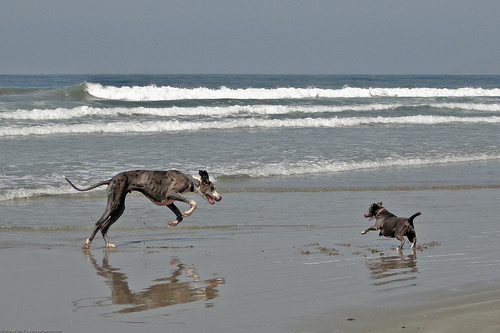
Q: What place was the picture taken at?
A: It was taken at the beach.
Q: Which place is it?
A: It is a beach.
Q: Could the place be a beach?
A: Yes, it is a beach.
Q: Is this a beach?
A: Yes, it is a beach.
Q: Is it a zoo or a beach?
A: It is a beach.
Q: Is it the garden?
A: No, it is the beach.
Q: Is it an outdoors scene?
A: Yes, it is outdoors.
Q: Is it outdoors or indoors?
A: It is outdoors.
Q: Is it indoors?
A: No, it is outdoors.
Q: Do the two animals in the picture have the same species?
A: Yes, all the animals are dogs.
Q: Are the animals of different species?
A: No, all the animals are dogs.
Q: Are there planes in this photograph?
A: No, there are no planes.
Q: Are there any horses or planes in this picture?
A: No, there are no planes or horses.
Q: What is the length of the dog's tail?
A: The tail is long.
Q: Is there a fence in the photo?
A: No, there are no fences.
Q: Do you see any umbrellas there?
A: No, there are no umbrellas.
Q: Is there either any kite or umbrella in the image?
A: No, there are no umbrellas or kites.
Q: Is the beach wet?
A: Yes, the beach is wet.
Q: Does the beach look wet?
A: Yes, the beach is wet.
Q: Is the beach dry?
A: No, the beach is wet.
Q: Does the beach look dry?
A: No, the beach is wet.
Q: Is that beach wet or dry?
A: The beach is wet.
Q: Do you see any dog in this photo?
A: Yes, there is a dog.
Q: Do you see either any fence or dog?
A: Yes, there is a dog.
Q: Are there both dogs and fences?
A: No, there is a dog but no fences.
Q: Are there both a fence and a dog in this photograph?
A: No, there is a dog but no fences.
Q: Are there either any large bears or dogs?
A: Yes, there is a large dog.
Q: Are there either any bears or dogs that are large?
A: Yes, the dog is large.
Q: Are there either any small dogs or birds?
A: Yes, there is a small dog.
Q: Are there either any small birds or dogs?
A: Yes, there is a small dog.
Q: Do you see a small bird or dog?
A: Yes, there is a small dog.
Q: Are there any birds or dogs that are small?
A: Yes, the dog is small.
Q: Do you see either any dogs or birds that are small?
A: Yes, the dog is small.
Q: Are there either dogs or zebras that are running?
A: Yes, the dog is running.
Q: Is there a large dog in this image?
A: Yes, there is a large dog.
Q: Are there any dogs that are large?
A: Yes, there is a dog that is large.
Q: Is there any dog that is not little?
A: Yes, there is a large dog.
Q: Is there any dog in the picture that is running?
A: Yes, there is a dog that is running.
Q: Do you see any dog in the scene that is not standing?
A: Yes, there is a dog that is running .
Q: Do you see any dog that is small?
A: Yes, there is a small dog.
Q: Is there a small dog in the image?
A: Yes, there is a small dog.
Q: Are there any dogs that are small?
A: Yes, there is a dog that is small.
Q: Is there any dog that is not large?
A: Yes, there is a small dog.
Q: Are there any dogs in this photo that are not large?
A: Yes, there is a small dog.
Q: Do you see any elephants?
A: No, there are no elephants.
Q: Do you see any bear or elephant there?
A: No, there are no elephants or bears.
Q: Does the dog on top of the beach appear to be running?
A: Yes, the dog is running.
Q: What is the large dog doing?
A: The dog is running.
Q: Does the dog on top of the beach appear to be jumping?
A: No, the dog is running.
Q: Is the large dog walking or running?
A: The dog is running.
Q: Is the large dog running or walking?
A: The dog is running.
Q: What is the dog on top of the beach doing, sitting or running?
A: The dog is running.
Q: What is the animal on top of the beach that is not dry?
A: The animal is a dog.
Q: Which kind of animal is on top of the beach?
A: The animal is a dog.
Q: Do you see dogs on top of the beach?
A: Yes, there is a dog on top of the beach.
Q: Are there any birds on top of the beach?
A: No, there is a dog on top of the beach.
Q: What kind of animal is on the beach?
A: The animal is a dog.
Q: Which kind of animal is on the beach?
A: The animal is a dog.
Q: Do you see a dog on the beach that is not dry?
A: Yes, there is a dog on the beach.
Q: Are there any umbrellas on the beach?
A: No, there is a dog on the beach.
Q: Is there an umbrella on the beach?
A: No, there is a dog on the beach.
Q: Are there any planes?
A: No, there are no planes.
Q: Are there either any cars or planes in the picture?
A: No, there are no planes or cars.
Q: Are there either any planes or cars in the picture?
A: No, there are no planes or cars.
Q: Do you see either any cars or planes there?
A: No, there are no planes or cars.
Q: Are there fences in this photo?
A: No, there are no fences.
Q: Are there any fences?
A: No, there are no fences.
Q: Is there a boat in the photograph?
A: No, there are no boats.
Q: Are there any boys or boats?
A: No, there are no boats or boys.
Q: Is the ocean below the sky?
A: Yes, the ocean is below the sky.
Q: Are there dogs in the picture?
A: Yes, there is a dog.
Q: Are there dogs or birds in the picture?
A: Yes, there is a dog.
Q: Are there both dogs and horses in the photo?
A: No, there is a dog but no horses.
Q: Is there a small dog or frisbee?
A: Yes, there is a small dog.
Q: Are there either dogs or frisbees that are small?
A: Yes, the dog is small.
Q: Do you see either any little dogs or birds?
A: Yes, there is a little dog.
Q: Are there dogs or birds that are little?
A: Yes, the dog is little.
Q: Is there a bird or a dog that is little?
A: Yes, the dog is little.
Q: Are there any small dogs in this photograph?
A: Yes, there is a small dog.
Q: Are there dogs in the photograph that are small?
A: Yes, there is a dog that is small.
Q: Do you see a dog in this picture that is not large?
A: Yes, there is a small dog.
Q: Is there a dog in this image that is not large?
A: Yes, there is a small dog.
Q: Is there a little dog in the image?
A: Yes, there is a little dog.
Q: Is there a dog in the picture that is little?
A: Yes, there is a dog that is little.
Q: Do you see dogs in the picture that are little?
A: Yes, there is a dog that is little.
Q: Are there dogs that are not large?
A: Yes, there is a little dog.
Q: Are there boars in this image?
A: No, there are no boars.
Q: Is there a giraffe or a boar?
A: No, there are no boars or giraffes.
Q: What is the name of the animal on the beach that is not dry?
A: The animal is a dog.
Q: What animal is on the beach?
A: The animal is a dog.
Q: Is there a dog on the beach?
A: Yes, there is a dog on the beach.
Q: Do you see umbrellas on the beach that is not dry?
A: No, there is a dog on the beach.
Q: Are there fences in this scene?
A: No, there are no fences.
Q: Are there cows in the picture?
A: No, there are no cows.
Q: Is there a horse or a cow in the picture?
A: No, there are no cows or horses.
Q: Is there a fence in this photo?
A: No, there are no fences.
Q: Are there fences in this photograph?
A: No, there are no fences.